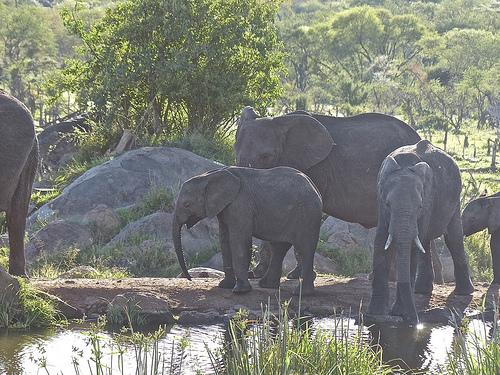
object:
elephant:
[172, 164, 324, 297]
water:
[1, 316, 499, 373]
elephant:
[369, 138, 472, 312]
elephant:
[235, 104, 436, 296]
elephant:
[0, 78, 38, 278]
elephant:
[461, 193, 499, 289]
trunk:
[396, 241, 420, 324]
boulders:
[0, 147, 476, 280]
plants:
[0, 282, 499, 375]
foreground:
[1, 267, 498, 375]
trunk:
[172, 219, 192, 278]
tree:
[60, 0, 290, 150]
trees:
[293, 3, 500, 126]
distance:
[0, 0, 499, 171]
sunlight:
[8, 320, 228, 374]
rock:
[317, 222, 362, 262]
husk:
[413, 235, 427, 253]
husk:
[383, 235, 393, 249]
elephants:
[172, 104, 499, 316]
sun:
[415, 321, 426, 330]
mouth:
[184, 220, 200, 230]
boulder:
[0, 146, 277, 271]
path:
[27, 274, 499, 312]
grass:
[217, 286, 404, 374]